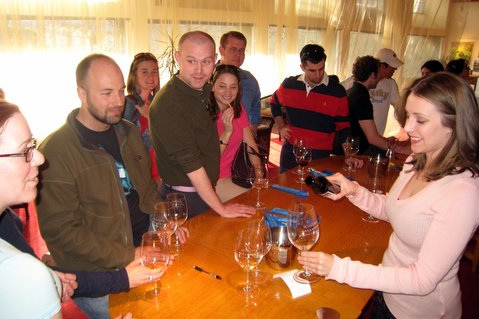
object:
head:
[76, 53, 125, 123]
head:
[175, 30, 218, 89]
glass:
[286, 202, 320, 284]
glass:
[234, 227, 265, 300]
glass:
[141, 231, 172, 305]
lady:
[294, 72, 479, 319]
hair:
[77, 54, 119, 89]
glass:
[293, 139, 310, 185]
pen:
[193, 266, 223, 280]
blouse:
[323, 154, 479, 319]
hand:
[220, 200, 257, 219]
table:
[109, 141, 406, 318]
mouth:
[408, 134, 423, 145]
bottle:
[295, 169, 345, 198]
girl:
[210, 63, 266, 204]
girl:
[119, 51, 165, 192]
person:
[0, 102, 84, 318]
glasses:
[1, 139, 39, 163]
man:
[266, 43, 356, 173]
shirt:
[270, 75, 352, 158]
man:
[36, 53, 165, 271]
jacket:
[35, 108, 165, 273]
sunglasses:
[132, 51, 157, 60]